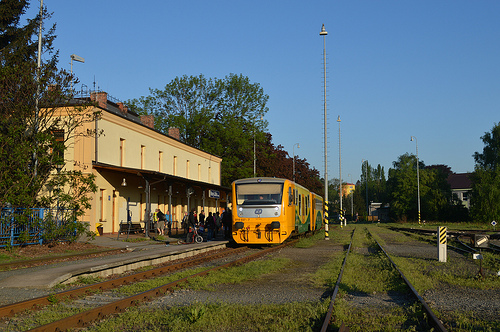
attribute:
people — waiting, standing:
[149, 207, 233, 248]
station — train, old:
[23, 89, 237, 246]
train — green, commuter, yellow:
[228, 174, 330, 251]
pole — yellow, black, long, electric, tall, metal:
[317, 18, 337, 240]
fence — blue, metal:
[2, 203, 77, 247]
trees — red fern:
[263, 142, 326, 196]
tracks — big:
[2, 193, 319, 329]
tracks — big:
[307, 216, 451, 331]